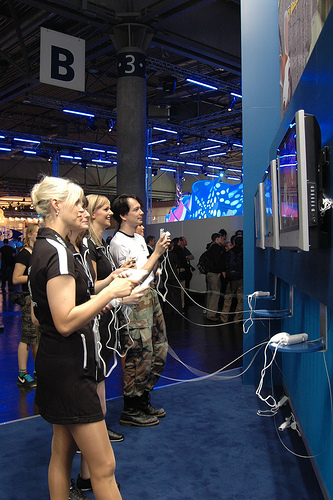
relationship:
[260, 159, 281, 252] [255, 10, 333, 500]
television on wall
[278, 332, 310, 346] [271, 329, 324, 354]
controller on shelf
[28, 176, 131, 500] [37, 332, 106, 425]
woman wearing a skirt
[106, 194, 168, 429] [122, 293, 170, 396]
man wearing pants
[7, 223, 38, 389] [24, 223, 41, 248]
woman has a head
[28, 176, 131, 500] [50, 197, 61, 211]
woman has an ear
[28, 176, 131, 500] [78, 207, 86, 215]
woman has a nose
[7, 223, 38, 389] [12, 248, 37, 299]
woman wearing a shirt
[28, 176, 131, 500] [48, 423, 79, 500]
woman has a leg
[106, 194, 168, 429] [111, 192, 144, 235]
man has a head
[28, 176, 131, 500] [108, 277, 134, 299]
woman has a hand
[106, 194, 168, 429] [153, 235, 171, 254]
man has a hand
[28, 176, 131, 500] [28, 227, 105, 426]
woman wearing a dress